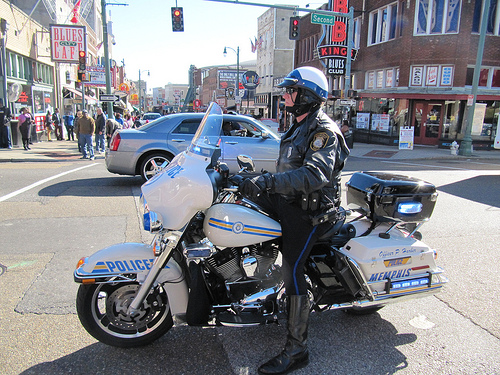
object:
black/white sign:
[101, 95, 119, 101]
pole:
[101, 0, 114, 121]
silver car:
[105, 113, 281, 182]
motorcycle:
[73, 102, 447, 348]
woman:
[18, 106, 34, 151]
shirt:
[18, 113, 31, 126]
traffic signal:
[293, 20, 298, 25]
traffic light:
[289, 16, 300, 40]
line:
[0, 162, 100, 202]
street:
[0, 140, 497, 375]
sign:
[311, 13, 336, 25]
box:
[345, 172, 438, 222]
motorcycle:
[261, 64, 346, 255]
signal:
[174, 9, 181, 17]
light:
[170, 6, 184, 32]